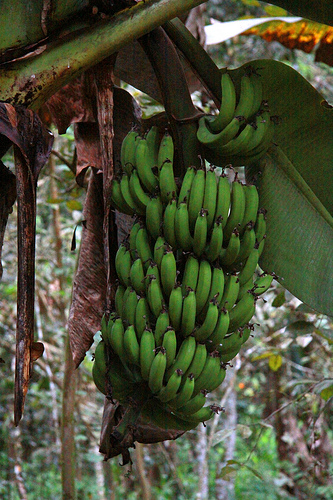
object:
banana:
[194, 207, 207, 257]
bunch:
[91, 70, 275, 431]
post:
[191, 430, 211, 498]